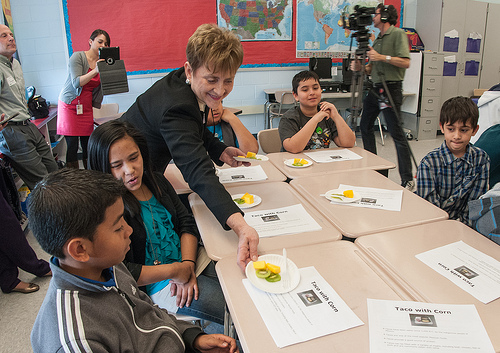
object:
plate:
[323, 187, 365, 204]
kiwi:
[255, 269, 272, 280]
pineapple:
[252, 260, 268, 271]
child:
[412, 95, 493, 228]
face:
[444, 122, 473, 150]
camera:
[340, 3, 376, 31]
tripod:
[344, 30, 418, 172]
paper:
[412, 239, 498, 305]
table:
[353, 218, 500, 353]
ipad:
[96, 46, 130, 95]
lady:
[119, 22, 259, 273]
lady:
[56, 28, 110, 170]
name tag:
[75, 103, 83, 114]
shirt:
[416, 139, 490, 227]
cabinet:
[402, 51, 447, 141]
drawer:
[422, 52, 450, 77]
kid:
[275, 70, 357, 155]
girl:
[87, 119, 225, 327]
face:
[109, 142, 144, 190]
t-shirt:
[277, 105, 339, 151]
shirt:
[138, 193, 184, 296]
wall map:
[215, 2, 293, 42]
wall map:
[295, 0, 385, 59]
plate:
[283, 157, 314, 169]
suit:
[119, 67, 244, 231]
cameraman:
[337, 2, 416, 191]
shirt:
[369, 24, 411, 83]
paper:
[364, 297, 499, 353]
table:
[214, 239, 422, 353]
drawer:
[422, 84, 444, 97]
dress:
[53, 66, 101, 138]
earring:
[185, 78, 191, 84]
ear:
[182, 60, 194, 84]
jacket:
[27, 254, 210, 353]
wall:
[13, 1, 66, 39]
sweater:
[123, 171, 201, 295]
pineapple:
[343, 189, 355, 198]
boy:
[21, 165, 238, 353]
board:
[60, 1, 406, 80]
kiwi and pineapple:
[252, 259, 283, 284]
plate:
[244, 253, 302, 295]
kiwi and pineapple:
[328, 189, 357, 201]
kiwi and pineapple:
[234, 191, 255, 205]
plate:
[230, 191, 264, 209]